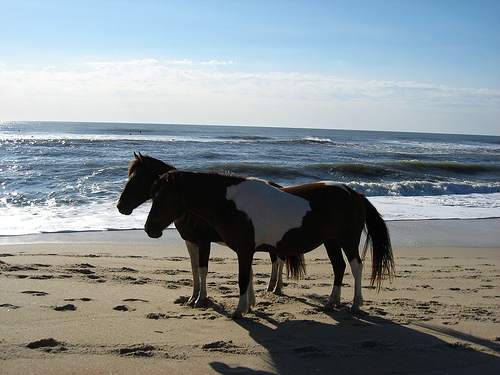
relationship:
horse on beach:
[144, 169, 397, 316] [74, 299, 135, 330]